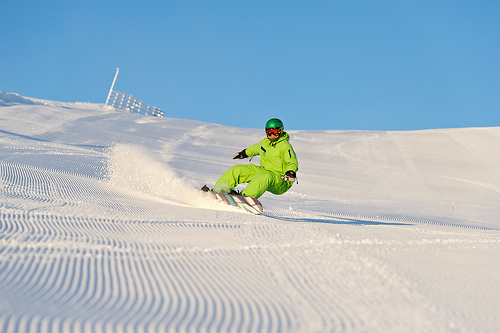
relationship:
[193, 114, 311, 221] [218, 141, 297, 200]
man in a snow suit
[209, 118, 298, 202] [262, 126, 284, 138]
man in goggles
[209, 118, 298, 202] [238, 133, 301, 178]
man in jacket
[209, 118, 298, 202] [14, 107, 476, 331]
man snowboarding snow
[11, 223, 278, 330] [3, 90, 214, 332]
treads in snow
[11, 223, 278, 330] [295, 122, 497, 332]
treads in snow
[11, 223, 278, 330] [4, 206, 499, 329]
treads in snow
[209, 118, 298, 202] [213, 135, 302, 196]
man wearing snowsuit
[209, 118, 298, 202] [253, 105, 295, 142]
man wearing helmet